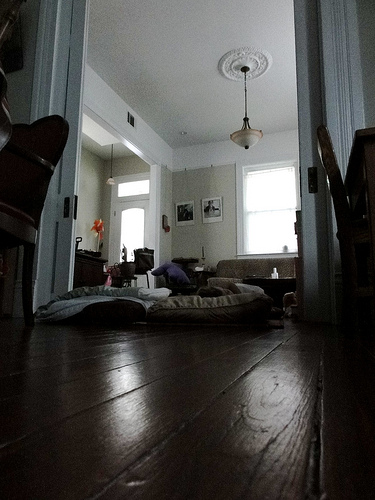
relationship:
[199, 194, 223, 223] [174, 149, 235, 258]
art hanging on wall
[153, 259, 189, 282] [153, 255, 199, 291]
pillow on chair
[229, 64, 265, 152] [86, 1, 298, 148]
lamp hanging from ceiling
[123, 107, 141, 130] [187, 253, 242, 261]
air vent attached to wall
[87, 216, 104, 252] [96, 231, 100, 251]
flower on stand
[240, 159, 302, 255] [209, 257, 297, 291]
window by sofa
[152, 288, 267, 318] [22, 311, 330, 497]
cushion on floor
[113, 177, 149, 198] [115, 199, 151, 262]
window over door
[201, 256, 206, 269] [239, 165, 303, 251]
candle stick left of window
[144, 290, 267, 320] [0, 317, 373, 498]
pillow on floor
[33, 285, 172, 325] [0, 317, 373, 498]
pillow on floor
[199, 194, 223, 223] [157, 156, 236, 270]
art on wall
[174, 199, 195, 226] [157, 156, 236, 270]
art on wall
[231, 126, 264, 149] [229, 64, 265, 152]
shade on lamp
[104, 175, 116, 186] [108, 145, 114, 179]
light on chain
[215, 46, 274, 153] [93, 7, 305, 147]
light fixture on roof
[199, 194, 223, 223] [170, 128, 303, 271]
art on wall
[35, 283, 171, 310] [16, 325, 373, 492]
pillows on floor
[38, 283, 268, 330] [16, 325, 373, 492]
dog bed on floor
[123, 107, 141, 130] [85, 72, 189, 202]
air vent on pillar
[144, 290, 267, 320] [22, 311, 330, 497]
pillow on floor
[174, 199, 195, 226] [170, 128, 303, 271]
art on wall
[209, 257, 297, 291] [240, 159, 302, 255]
sofa by window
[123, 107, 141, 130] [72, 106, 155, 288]
air vent above door frame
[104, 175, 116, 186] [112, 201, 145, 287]
light by door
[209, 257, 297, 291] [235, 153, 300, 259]
sofa by window